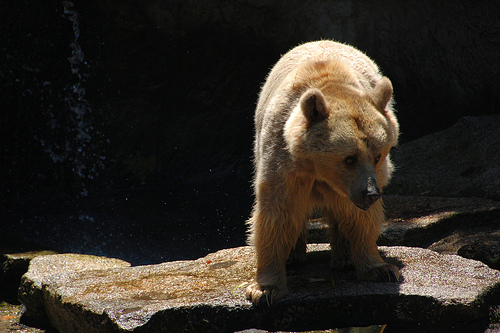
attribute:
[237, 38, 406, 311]
bear — brown, white, standing, looking, waiting, polar bear, furry, looking left, sunlit, sad looking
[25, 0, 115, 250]
water — dripping, falling, splashing, trickling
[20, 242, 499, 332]
rock — grey, flat, brown, large, sunlit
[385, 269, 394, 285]
claw — long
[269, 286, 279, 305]
claw — long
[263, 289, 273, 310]
claw — long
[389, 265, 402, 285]
claw — long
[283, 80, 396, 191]
ruff — cream colored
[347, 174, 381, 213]
snout — long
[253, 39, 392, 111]
back — sunlit, furry, white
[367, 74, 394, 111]
ear — fluffy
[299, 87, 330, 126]
ear — fluffy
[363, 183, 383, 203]
nose — black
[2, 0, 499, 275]
background — dark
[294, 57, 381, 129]
fur — darker